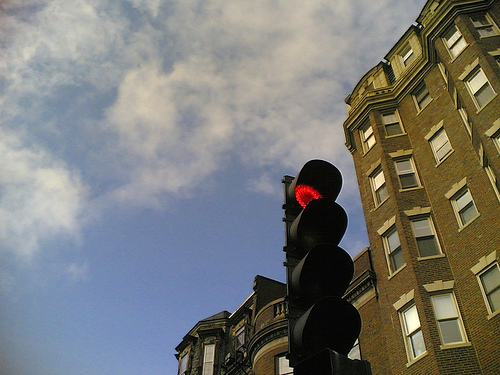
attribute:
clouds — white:
[148, 11, 335, 80]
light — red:
[285, 158, 342, 216]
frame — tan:
[444, 173, 464, 198]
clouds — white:
[3, 145, 100, 257]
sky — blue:
[3, 0, 283, 297]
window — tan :
[418, 123, 459, 165]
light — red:
[268, 152, 393, 374]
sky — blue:
[6, 3, 287, 268]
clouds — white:
[65, 29, 245, 147]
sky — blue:
[23, 17, 406, 321]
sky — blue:
[3, 27, 247, 307]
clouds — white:
[0, 0, 430, 303]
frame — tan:
[422, 275, 474, 352]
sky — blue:
[15, 18, 364, 328]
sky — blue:
[5, 7, 411, 374]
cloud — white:
[60, 252, 100, 291]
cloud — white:
[97, 56, 246, 224]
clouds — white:
[129, 19, 271, 180]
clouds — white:
[117, 63, 195, 162]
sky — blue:
[104, 233, 246, 281]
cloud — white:
[4, 137, 94, 259]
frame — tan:
[382, 144, 427, 197]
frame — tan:
[416, 115, 460, 173]